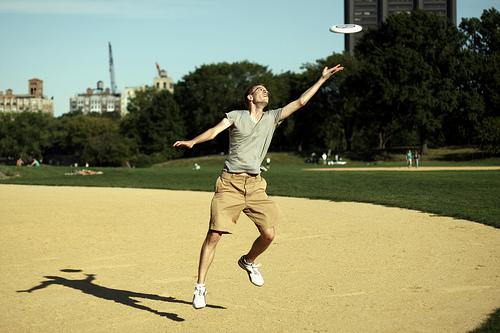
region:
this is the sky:
[27, 12, 94, 72]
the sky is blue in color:
[15, 17, 70, 67]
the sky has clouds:
[29, 14, 96, 79]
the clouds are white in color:
[164, 9, 224, 39]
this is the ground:
[104, 194, 139, 230]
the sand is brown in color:
[302, 220, 366, 279]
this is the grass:
[391, 166, 427, 188]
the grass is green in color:
[372, 175, 433, 201]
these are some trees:
[372, 17, 487, 160]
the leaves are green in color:
[384, 28, 426, 106]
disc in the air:
[311, 23, 375, 43]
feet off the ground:
[186, 254, 276, 313]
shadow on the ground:
[39, 257, 179, 322]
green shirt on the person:
[229, 110, 266, 171]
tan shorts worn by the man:
[217, 181, 267, 239]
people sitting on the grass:
[0, 150, 56, 177]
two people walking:
[398, 146, 431, 176]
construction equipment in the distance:
[105, 34, 125, 99]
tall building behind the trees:
[351, 0, 465, 14]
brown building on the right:
[0, 76, 64, 113]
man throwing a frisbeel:
[195, 44, 367, 304]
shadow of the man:
[51, 241, 181, 331]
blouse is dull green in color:
[231, 112, 271, 166]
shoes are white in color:
[188, 279, 216, 306]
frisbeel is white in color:
[329, 11, 366, 43]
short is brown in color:
[209, 164, 262, 226]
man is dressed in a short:
[207, 91, 295, 278]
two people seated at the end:
[16, 138, 56, 175]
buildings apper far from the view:
[76, 79, 139, 116]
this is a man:
[156, 64, 325, 307]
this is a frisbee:
[331, 15, 375, 42]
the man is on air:
[160, 55, 344, 309]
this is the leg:
[234, 218, 279, 281]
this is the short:
[211, 180, 270, 225]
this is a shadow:
[29, 263, 170, 309]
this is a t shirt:
[229, 120, 269, 167]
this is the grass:
[403, 171, 468, 207]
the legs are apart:
[194, 206, 278, 292]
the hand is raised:
[290, 57, 343, 121]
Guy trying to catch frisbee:
[177, 7, 367, 319]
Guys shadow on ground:
[18, 250, 217, 331]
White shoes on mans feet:
[165, 257, 290, 317]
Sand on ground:
[6, 184, 210, 268]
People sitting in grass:
[6, 139, 56, 179]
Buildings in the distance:
[8, 47, 164, 117]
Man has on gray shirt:
[213, 102, 286, 192]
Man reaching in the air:
[192, 56, 349, 316]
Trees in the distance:
[8, 83, 220, 180]